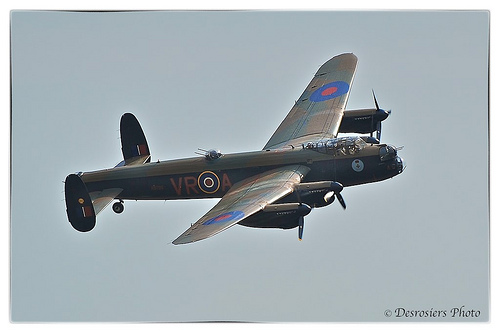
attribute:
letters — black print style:
[169, 168, 232, 199]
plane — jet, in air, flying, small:
[60, 46, 406, 247]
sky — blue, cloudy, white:
[14, 15, 492, 322]